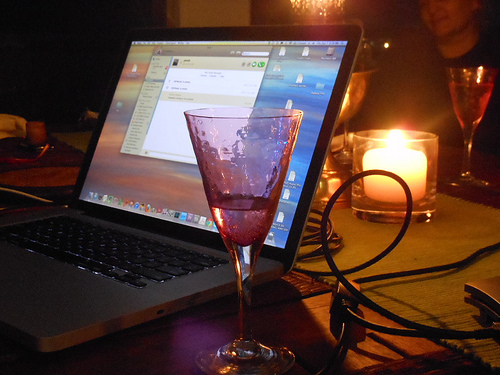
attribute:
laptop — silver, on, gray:
[1, 24, 365, 352]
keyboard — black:
[1, 215, 231, 288]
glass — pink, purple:
[184, 106, 304, 374]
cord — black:
[297, 169, 500, 374]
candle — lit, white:
[362, 126, 427, 205]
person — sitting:
[416, 0, 500, 157]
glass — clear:
[350, 129, 438, 224]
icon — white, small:
[101, 194, 109, 203]